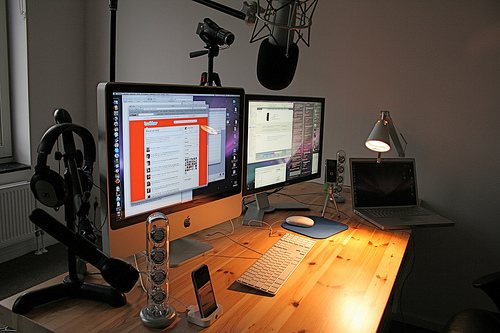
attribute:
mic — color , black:
[27, 205, 139, 295]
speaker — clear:
[332, 151, 352, 193]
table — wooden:
[49, 172, 420, 329]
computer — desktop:
[91, 77, 244, 257]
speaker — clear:
[135, 207, 176, 327]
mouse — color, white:
[288, 216, 313, 226]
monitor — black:
[245, 90, 328, 200]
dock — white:
[178, 300, 238, 328]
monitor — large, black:
[245, 88, 330, 212]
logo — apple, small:
[181, 215, 192, 228]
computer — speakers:
[41, 64, 359, 234]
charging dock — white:
[186, 298, 223, 326]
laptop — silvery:
[354, 148, 451, 228]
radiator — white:
[0, 179, 46, 260]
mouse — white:
[285, 215, 315, 227]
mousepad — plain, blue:
[284, 216, 347, 239]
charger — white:
[188, 302, 223, 327]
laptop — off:
[347, 152, 459, 232]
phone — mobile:
[189, 263, 221, 317]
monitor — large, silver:
[93, 74, 253, 264]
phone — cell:
[193, 263, 221, 313]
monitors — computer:
[102, 83, 398, 191]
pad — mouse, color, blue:
[325, 218, 348, 248]